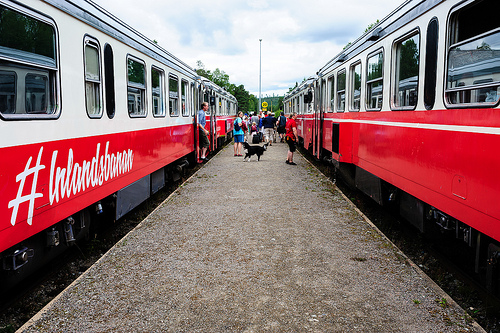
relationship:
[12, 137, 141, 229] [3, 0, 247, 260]
logo in train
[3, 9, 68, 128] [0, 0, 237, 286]
window on train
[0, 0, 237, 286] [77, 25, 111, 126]
train has window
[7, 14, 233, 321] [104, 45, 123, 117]
train has window